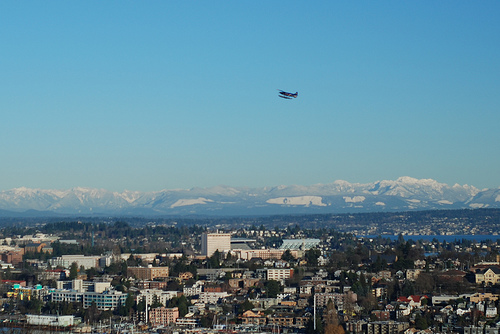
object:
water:
[355, 235, 500, 243]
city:
[0, 230, 500, 334]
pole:
[313, 295, 316, 332]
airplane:
[277, 88, 299, 99]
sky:
[0, 0, 500, 191]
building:
[6, 284, 46, 303]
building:
[201, 228, 231, 258]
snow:
[0, 176, 500, 212]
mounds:
[10, 283, 44, 290]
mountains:
[0, 175, 500, 218]